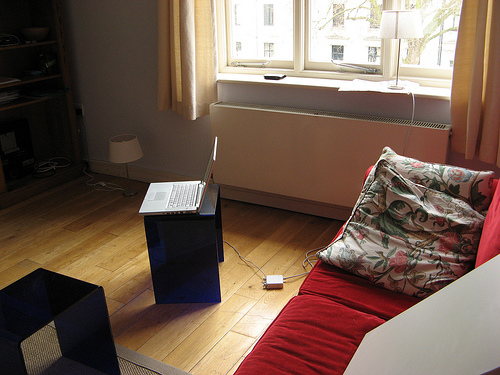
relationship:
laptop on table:
[137, 136, 217, 217] [136, 217, 243, 304]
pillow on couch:
[319, 163, 487, 297] [229, 150, 499, 374]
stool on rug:
[6, 264, 124, 358] [0, 298, 218, 373]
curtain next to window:
[158, 2, 214, 117] [214, 2, 449, 78]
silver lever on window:
[333, 52, 387, 79] [214, 2, 449, 78]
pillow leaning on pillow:
[319, 163, 487, 297] [385, 138, 499, 207]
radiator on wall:
[215, 110, 443, 208] [88, 2, 183, 181]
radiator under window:
[215, 110, 443, 208] [214, 2, 449, 78]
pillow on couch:
[344, 146, 495, 225] [229, 150, 499, 374]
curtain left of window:
[158, 0, 214, 123] [214, 2, 449, 78]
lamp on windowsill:
[373, 4, 431, 95] [225, 69, 459, 95]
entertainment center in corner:
[0, 5, 90, 206] [0, 0, 122, 200]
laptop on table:
[131, 163, 268, 318] [141, 216, 269, 304]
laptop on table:
[137, 136, 217, 217] [136, 176, 228, 306]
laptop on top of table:
[137, 136, 217, 217] [119, 125, 235, 315]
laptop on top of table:
[137, 136, 217, 217] [140, 217, 239, 307]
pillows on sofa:
[361, 141, 473, 305] [315, 116, 478, 355]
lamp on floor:
[88, 124, 148, 216] [2, 167, 343, 373]